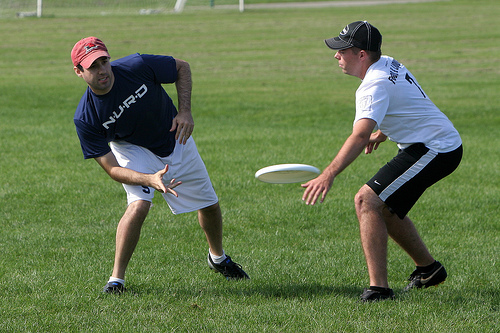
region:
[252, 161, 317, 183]
a frisbee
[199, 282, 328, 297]
a shadow on the grass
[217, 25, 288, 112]
a field of grass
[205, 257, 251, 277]
the mans shoe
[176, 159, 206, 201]
the man is wearing white shorts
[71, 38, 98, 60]
a red hat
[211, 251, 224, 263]
white socks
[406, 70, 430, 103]
a number on the shirt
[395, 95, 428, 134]
the shirt is white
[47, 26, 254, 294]
the man on the grass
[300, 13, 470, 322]
the man on the grass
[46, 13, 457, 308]
the men playing with the frisbee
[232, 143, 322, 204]
the frisbee is white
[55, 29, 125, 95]
the hat is red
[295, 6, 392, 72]
the man wearing the black hat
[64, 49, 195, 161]
the man wearing the blue shirt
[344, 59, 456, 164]
the man wearing the white t shirt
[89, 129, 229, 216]
the man wearing the white shorts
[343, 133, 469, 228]
the man wearing black shorts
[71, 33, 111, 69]
a red cap on a man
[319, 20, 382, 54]
a black cap on a man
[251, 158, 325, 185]
a white frisbee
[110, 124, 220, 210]
white shorts on a man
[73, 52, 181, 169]
a navy shirt with white letters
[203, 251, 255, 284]
a black shoe on a man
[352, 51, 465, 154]
a white shirt on a man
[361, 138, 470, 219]
black shorts with a white stripe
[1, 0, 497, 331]
a green grassy field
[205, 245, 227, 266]
a white sock on a man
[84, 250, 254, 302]
Man wearing shoes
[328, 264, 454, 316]
Man wearing black and white shoes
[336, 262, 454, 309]
Man is wearing shoes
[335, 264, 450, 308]
Man is wearing black and white shoes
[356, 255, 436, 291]
Man wearing socks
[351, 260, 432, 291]
Man is wearing socks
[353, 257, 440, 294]
Man wearing black socks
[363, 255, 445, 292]
Man is wearing black socks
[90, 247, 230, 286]
Man wearing white socks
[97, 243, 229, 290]
Man is wearing white socks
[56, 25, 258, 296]
this man is bending over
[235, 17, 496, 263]
this man is catching a frisbee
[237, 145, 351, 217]
the frisbee has been thrown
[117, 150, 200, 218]
hand throwing a frisbee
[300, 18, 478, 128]
the baseball hat is black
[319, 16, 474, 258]
the man has nike shorts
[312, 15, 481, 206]
the man's shirt is 7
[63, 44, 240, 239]
this man has white shorts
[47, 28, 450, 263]
two men play frisbee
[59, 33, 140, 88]
the man's hat is red